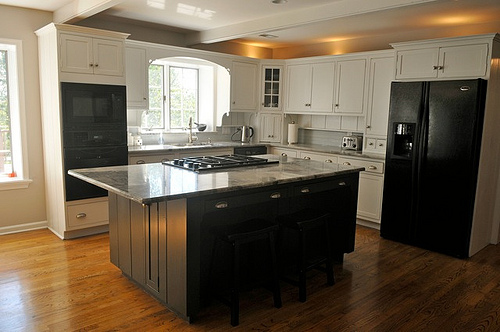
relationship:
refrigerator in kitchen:
[381, 81, 483, 258] [1, 22, 496, 328]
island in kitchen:
[69, 154, 364, 319] [1, 22, 496, 328]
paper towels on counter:
[286, 122, 300, 144] [273, 139, 383, 164]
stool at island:
[211, 219, 282, 328] [69, 154, 364, 319]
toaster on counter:
[340, 135, 363, 152] [273, 139, 383, 164]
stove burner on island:
[166, 153, 279, 169] [69, 154, 364, 319]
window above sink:
[166, 64, 201, 132] [169, 141, 212, 147]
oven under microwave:
[62, 129, 129, 194] [61, 82, 127, 127]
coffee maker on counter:
[232, 124, 254, 143] [216, 139, 266, 147]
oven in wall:
[62, 129, 129, 194] [36, 22, 130, 239]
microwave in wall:
[61, 82, 127, 127] [36, 22, 130, 239]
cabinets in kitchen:
[287, 62, 369, 115] [1, 22, 496, 328]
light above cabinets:
[247, 41, 355, 60] [287, 62, 369, 115]